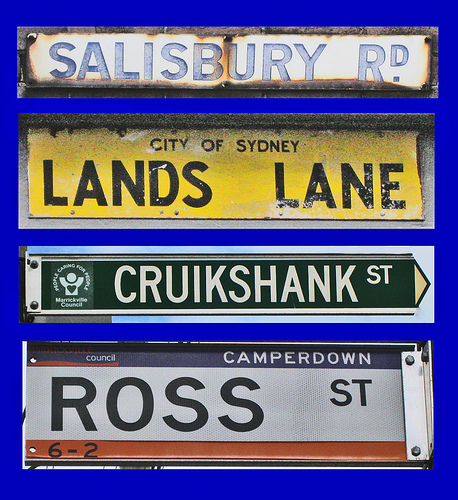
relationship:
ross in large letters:
[35, 374, 273, 438] [40, 355, 257, 440]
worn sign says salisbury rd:
[3, 15, 441, 109] [46, 32, 409, 84]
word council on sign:
[82, 353, 121, 363] [16, 339, 429, 473]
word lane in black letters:
[266, 157, 409, 210] [260, 158, 417, 219]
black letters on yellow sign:
[260, 158, 417, 219] [21, 123, 421, 220]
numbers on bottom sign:
[41, 436, 101, 463] [13, 332, 439, 474]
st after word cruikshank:
[366, 263, 395, 287] [110, 260, 358, 304]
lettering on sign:
[41, 147, 411, 216] [18, 108, 429, 222]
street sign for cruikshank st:
[12, 234, 440, 333] [28, 252, 419, 310]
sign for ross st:
[16, 339, 429, 473] [30, 349, 416, 438]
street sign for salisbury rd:
[17, 25, 443, 103] [41, 35, 411, 86]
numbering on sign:
[43, 437, 102, 459] [22, 339, 418, 468]